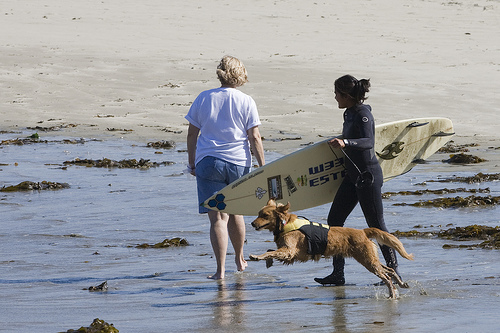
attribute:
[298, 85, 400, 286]
wetsuit — black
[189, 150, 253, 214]
shorts — blue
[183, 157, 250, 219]
shorts — blue, jeans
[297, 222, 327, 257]
jacket — blue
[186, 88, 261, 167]
shirt — white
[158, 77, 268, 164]
t shirt — white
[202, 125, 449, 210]
surfboard — white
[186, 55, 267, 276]
woman — barefoot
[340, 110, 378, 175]
wetsuit — black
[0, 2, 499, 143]
sand — gray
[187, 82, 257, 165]
shirt — white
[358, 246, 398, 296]
leg — wet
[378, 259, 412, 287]
leg — wet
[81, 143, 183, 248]
water — shallow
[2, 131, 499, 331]
water — shallow